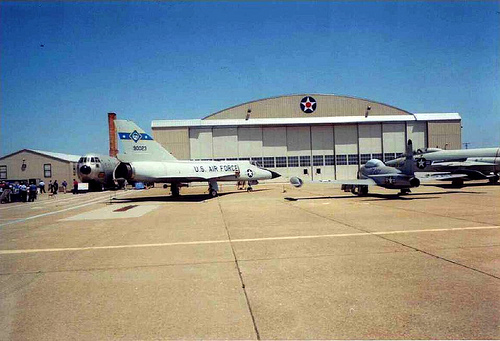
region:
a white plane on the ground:
[101, 112, 287, 198]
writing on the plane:
[190, 162, 245, 172]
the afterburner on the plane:
[116, 159, 133, 181]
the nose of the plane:
[269, 165, 283, 181]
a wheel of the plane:
[206, 184, 219, 199]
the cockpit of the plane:
[247, 157, 266, 170]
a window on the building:
[286, 151, 300, 169]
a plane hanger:
[148, 91, 477, 190]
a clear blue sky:
[0, 0, 499, 157]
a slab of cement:
[229, 237, 499, 339]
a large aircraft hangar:
[150, 91, 464, 183]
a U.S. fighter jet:
[113, 116, 280, 195]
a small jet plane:
[286, 137, 479, 196]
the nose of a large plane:
[76, 151, 118, 192]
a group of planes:
[77, 109, 498, 196]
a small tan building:
[1, 147, 81, 192]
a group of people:
[0, 176, 80, 204]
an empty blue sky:
[2, 0, 498, 159]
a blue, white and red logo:
[299, 94, 318, 114]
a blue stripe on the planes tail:
[117, 127, 155, 142]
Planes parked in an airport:
[108, 101, 498, 198]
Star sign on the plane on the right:
[415, 155, 422, 165]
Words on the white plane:
[190, 160, 240, 170]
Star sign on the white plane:
[245, 165, 250, 175]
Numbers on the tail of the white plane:
[130, 141, 141, 146]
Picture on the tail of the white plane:
[116, 127, 153, 142]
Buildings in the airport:
[0, 92, 462, 192]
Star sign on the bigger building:
[298, 94, 317, 113]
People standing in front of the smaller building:
[2, 178, 79, 200]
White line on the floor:
[0, 225, 498, 255]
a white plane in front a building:
[94, 105, 291, 213]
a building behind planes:
[149, 79, 482, 152]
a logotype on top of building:
[296, 93, 324, 115]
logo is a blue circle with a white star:
[291, 91, 324, 118]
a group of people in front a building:
[2, 168, 79, 210]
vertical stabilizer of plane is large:
[106, 114, 177, 163]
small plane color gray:
[311, 134, 427, 209]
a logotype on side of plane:
[243, 164, 256, 179]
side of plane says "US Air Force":
[174, 154, 251, 181]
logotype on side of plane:
[410, 153, 433, 173]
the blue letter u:
[191, 164, 201, 173]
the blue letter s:
[199, 164, 207, 174]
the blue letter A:
[204, 163, 214, 173]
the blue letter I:
[210, 163, 217, 173]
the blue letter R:
[210, 163, 218, 168]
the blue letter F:
[217, 162, 227, 178]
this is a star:
[295, 88, 322, 121]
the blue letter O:
[222, 162, 229, 172]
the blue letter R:
[226, 163, 233, 172]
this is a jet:
[71, 93, 286, 215]